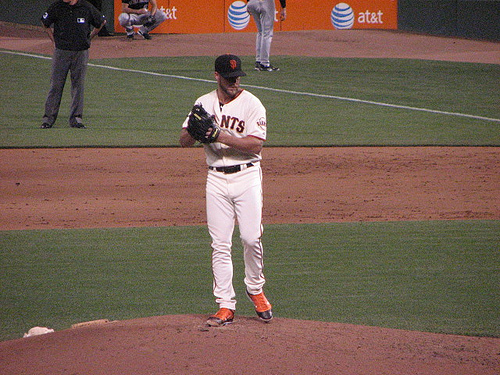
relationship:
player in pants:
[245, 0, 285, 76] [242, 0, 273, 66]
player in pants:
[114, 2, 169, 42] [117, 8, 167, 39]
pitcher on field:
[178, 54, 274, 326] [2, 20, 499, 373]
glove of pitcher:
[187, 105, 226, 152] [176, 40, 269, 145]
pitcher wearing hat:
[178, 49, 274, 326] [213, 52, 246, 77]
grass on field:
[6, 212, 498, 347] [2, 20, 499, 373]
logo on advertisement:
[331, 0, 355, 29] [115, 0, 395, 35]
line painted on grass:
[3, 46, 498, 122] [0, 46, 499, 143]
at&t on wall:
[356, 10, 383, 26] [288, 0, 395, 36]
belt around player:
[201, 160, 261, 179] [175, 45, 296, 331]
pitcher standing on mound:
[178, 49, 274, 326] [0, 313, 499, 374]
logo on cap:
[229, 59, 236, 69] [214, 53, 247, 79]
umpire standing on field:
[38, 3, 103, 129] [2, 20, 499, 373]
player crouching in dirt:
[114, 1, 173, 44] [93, 32, 495, 63]